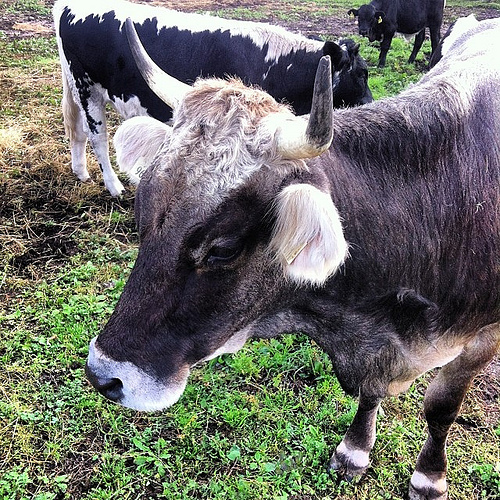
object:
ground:
[3, 0, 489, 495]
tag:
[130, 156, 149, 182]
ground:
[58, 425, 112, 465]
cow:
[45, 55, 498, 417]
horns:
[122, 16, 332, 162]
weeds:
[0, 0, 499, 500]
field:
[0, 3, 499, 495]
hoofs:
[331, 434, 373, 482]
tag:
[281, 222, 316, 264]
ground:
[450, 146, 465, 159]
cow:
[106, 132, 384, 392]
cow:
[230, 16, 332, 114]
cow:
[348, 0, 445, 67]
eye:
[202, 236, 243, 265]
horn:
[274, 56, 334, 163]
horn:
[125, 11, 195, 110]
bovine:
[44, 17, 474, 436]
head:
[83, 20, 353, 413]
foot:
[408, 454, 449, 499]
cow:
[53, 6, 373, 204]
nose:
[85, 361, 123, 401]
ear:
[274, 171, 349, 288]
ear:
[113, 116, 170, 181]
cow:
[87, 17, 497, 494]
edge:
[321, 192, 352, 286]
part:
[101, 378, 124, 402]